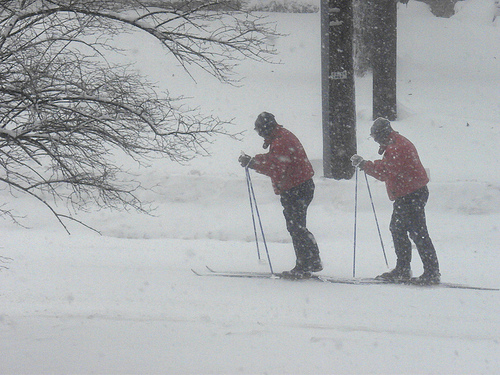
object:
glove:
[348, 155, 363, 170]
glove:
[235, 153, 251, 168]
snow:
[151, 190, 239, 252]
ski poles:
[362, 158, 390, 280]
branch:
[1, 181, 103, 239]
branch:
[55, 175, 160, 203]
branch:
[1, 123, 193, 167]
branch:
[2, 87, 250, 114]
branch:
[1, 2, 286, 42]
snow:
[263, 209, 363, 241]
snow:
[77, 28, 125, 117]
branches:
[168, 63, 202, 86]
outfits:
[352, 132, 442, 288]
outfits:
[239, 127, 339, 278]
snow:
[8, 253, 110, 355]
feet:
[377, 267, 412, 287]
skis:
[326, 271, 498, 298]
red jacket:
[243, 122, 316, 194]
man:
[217, 91, 327, 282]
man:
[350, 115, 441, 285]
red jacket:
[363, 130, 429, 200]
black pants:
[389, 184, 440, 279]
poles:
[350, 171, 357, 282]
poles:
[363, 176, 390, 276]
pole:
[309, 0, 371, 189]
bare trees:
[1, 0, 281, 235]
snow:
[405, 309, 500, 374]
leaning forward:
[233, 109, 332, 278]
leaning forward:
[358, 117, 438, 279]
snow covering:
[213, 81, 468, 279]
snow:
[132, 282, 408, 373]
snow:
[153, 257, 247, 318]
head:
[252, 109, 279, 141]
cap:
[256, 111, 279, 135]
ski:
[186, 267, 355, 281]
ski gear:
[240, 111, 320, 276]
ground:
[6, 13, 492, 371]